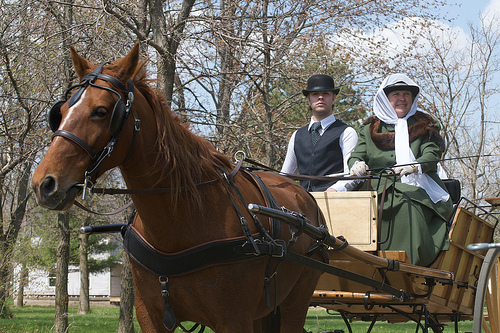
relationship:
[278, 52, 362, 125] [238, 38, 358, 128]
leaves on tree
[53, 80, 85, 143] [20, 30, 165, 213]
marker on head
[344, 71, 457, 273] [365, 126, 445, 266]
woman in jacket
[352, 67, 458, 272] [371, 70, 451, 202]
woman with scarf